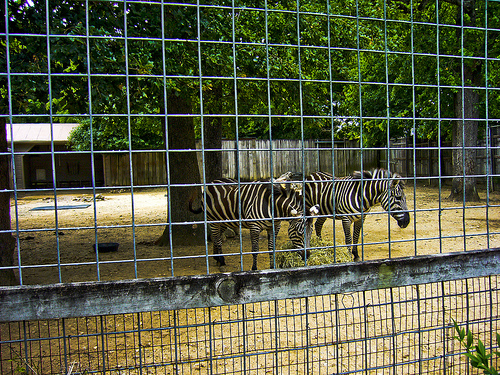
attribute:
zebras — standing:
[185, 166, 422, 275]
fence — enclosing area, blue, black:
[4, 1, 495, 160]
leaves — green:
[237, 26, 279, 70]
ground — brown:
[192, 264, 403, 347]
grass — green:
[281, 244, 358, 274]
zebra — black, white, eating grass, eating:
[188, 172, 336, 275]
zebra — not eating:
[301, 160, 421, 266]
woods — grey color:
[204, 130, 221, 161]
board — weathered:
[229, 132, 317, 176]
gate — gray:
[376, 138, 439, 176]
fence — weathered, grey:
[104, 141, 164, 187]